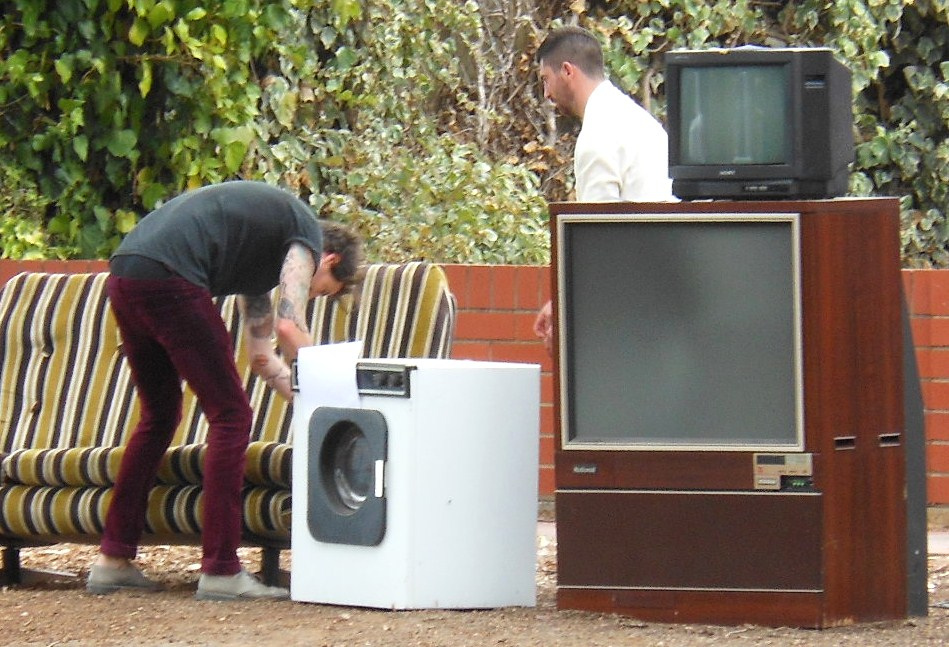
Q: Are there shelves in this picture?
A: No, there are no shelves.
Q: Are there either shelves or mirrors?
A: No, there are no shelves or mirrors.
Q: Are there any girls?
A: No, there are no girls.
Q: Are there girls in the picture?
A: No, there are no girls.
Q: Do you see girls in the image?
A: No, there are no girls.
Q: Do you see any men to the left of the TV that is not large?
A: Yes, there is a man to the left of the TV.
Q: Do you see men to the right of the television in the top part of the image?
A: No, the man is to the left of the television.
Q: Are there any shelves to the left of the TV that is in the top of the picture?
A: No, there is a man to the left of the television.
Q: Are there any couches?
A: Yes, there is a couch.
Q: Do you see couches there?
A: Yes, there is a couch.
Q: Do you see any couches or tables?
A: Yes, there is a couch.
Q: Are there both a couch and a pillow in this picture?
A: No, there is a couch but no pillows.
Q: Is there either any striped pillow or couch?
A: Yes, there is a striped couch.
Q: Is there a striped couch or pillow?
A: Yes, there is a striped couch.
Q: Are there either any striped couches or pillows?
A: Yes, there is a striped couch.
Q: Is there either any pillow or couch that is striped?
A: Yes, the couch is striped.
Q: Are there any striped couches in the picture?
A: Yes, there is a striped couch.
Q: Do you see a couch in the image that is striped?
A: Yes, there is a couch that is striped.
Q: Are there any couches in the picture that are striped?
A: Yes, there is a couch that is striped.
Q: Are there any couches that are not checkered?
A: Yes, there is a striped couch.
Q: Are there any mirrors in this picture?
A: No, there are no mirrors.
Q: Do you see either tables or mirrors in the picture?
A: No, there are no mirrors or tables.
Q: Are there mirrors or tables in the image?
A: No, there are no mirrors or tables.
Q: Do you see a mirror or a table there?
A: No, there are no mirrors or tables.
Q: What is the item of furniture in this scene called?
A: The piece of furniture is a couch.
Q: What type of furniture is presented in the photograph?
A: The furniture is a couch.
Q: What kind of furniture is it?
A: The piece of furniture is a couch.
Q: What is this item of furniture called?
A: This is a couch.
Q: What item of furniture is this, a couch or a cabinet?
A: This is a couch.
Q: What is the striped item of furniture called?
A: The piece of furniture is a couch.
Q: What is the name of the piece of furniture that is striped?
A: The piece of furniture is a couch.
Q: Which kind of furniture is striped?
A: The furniture is a couch.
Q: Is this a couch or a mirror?
A: This is a couch.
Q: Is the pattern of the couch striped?
A: Yes, the couch is striped.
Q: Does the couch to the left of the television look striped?
A: Yes, the couch is striped.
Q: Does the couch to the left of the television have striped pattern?
A: Yes, the couch is striped.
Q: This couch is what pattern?
A: The couch is striped.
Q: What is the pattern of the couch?
A: The couch is striped.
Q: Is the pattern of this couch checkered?
A: No, the couch is striped.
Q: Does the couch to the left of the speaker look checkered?
A: No, the couch is striped.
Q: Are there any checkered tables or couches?
A: No, there is a couch but it is striped.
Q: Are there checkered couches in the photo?
A: No, there is a couch but it is striped.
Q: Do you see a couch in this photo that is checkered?
A: No, there is a couch but it is striped.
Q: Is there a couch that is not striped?
A: No, there is a couch but it is striped.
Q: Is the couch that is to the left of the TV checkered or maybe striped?
A: The couch is striped.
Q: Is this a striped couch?
A: Yes, this is a striped couch.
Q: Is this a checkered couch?
A: No, this is a striped couch.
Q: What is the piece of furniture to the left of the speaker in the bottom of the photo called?
A: The piece of furniture is a couch.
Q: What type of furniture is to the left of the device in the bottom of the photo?
A: The piece of furniture is a couch.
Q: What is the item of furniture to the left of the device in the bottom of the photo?
A: The piece of furniture is a couch.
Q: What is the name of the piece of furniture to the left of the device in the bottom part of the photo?
A: The piece of furniture is a couch.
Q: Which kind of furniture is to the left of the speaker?
A: The piece of furniture is a couch.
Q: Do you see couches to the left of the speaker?
A: Yes, there is a couch to the left of the speaker.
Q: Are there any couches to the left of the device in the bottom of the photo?
A: Yes, there is a couch to the left of the speaker.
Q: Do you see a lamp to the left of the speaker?
A: No, there is a couch to the left of the speaker.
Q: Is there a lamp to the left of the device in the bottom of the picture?
A: No, there is a couch to the left of the speaker.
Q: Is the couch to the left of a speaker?
A: Yes, the couch is to the left of a speaker.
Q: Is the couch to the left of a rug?
A: No, the couch is to the left of a speaker.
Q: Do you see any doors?
A: Yes, there is a door.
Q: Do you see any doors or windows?
A: Yes, there is a door.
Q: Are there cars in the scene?
A: No, there are no cars.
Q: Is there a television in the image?
A: Yes, there is a television.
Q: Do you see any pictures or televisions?
A: Yes, there is a television.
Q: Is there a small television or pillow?
A: Yes, there is a small television.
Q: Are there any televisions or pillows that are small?
A: Yes, the television is small.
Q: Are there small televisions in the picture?
A: Yes, there is a small television.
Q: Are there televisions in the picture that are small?
A: Yes, there is a television that is small.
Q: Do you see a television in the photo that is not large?
A: Yes, there is a small television.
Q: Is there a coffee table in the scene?
A: No, there are no coffee tables.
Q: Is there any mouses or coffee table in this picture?
A: No, there are no coffee tables or computer mousess.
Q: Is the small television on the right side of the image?
A: Yes, the TV is on the right of the image.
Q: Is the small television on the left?
A: No, the TV is on the right of the image.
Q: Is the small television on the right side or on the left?
A: The TV is on the right of the image.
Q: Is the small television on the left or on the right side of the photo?
A: The TV is on the right of the image.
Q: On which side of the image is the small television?
A: The TV is on the right of the image.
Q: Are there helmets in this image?
A: No, there are no helmets.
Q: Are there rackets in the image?
A: No, there are no rackets.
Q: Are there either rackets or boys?
A: No, there are no rackets or boys.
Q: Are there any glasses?
A: No, there are no glasses.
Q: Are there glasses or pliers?
A: No, there are no glasses or pliers.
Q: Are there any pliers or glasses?
A: No, there are no glasses or pliers.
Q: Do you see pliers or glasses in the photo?
A: No, there are no glasses or pliers.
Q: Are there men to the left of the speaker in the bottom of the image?
A: Yes, there is a man to the left of the speaker.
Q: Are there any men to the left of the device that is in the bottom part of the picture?
A: Yes, there is a man to the left of the speaker.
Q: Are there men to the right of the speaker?
A: No, the man is to the left of the speaker.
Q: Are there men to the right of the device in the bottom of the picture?
A: No, the man is to the left of the speaker.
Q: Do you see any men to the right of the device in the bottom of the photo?
A: No, the man is to the left of the speaker.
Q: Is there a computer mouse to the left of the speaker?
A: No, there is a man to the left of the speaker.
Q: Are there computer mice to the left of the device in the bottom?
A: No, there is a man to the left of the speaker.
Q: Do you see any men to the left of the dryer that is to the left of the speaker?
A: Yes, there is a man to the left of the dryer.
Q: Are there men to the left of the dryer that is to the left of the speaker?
A: Yes, there is a man to the left of the dryer.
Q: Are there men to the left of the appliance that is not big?
A: Yes, there is a man to the left of the dryer.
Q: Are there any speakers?
A: Yes, there is a speaker.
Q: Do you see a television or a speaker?
A: Yes, there is a speaker.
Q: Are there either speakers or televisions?
A: Yes, there is a speaker.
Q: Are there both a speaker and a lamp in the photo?
A: No, there is a speaker but no lamps.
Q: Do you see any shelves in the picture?
A: No, there are no shelves.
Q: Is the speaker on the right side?
A: Yes, the speaker is on the right of the image.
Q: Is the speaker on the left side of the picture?
A: No, the speaker is on the right of the image.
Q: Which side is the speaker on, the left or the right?
A: The speaker is on the right of the image.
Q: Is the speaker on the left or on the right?
A: The speaker is on the right of the image.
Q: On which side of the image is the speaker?
A: The speaker is on the right of the image.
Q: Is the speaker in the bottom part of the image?
A: Yes, the speaker is in the bottom of the image.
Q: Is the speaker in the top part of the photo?
A: No, the speaker is in the bottom of the image.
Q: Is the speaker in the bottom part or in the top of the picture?
A: The speaker is in the bottom of the image.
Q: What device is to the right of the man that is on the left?
A: The device is a speaker.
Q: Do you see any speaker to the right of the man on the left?
A: Yes, there is a speaker to the right of the man.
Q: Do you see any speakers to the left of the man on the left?
A: No, the speaker is to the right of the man.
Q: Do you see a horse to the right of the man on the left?
A: No, there is a speaker to the right of the man.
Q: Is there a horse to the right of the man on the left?
A: No, there is a speaker to the right of the man.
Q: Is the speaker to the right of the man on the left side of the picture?
A: Yes, the speaker is to the right of the man.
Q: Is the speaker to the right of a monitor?
A: No, the speaker is to the right of the man.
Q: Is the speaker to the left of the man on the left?
A: No, the speaker is to the right of the man.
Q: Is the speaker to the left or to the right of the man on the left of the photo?
A: The speaker is to the right of the man.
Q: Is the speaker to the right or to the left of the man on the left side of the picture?
A: The speaker is to the right of the man.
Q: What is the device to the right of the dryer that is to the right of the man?
A: The device is a speaker.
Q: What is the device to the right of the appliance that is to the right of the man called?
A: The device is a speaker.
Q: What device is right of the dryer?
A: The device is a speaker.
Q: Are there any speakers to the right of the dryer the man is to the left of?
A: Yes, there is a speaker to the right of the dryer.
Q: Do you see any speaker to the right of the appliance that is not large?
A: Yes, there is a speaker to the right of the dryer.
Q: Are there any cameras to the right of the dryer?
A: No, there is a speaker to the right of the dryer.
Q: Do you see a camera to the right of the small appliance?
A: No, there is a speaker to the right of the dryer.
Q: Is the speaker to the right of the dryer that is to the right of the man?
A: Yes, the speaker is to the right of the dryer.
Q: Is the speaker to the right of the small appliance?
A: Yes, the speaker is to the right of the dryer.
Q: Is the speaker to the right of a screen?
A: No, the speaker is to the right of the dryer.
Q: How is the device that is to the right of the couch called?
A: The device is a speaker.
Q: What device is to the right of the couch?
A: The device is a speaker.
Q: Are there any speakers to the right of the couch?
A: Yes, there is a speaker to the right of the couch.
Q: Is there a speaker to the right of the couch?
A: Yes, there is a speaker to the right of the couch.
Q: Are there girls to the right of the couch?
A: No, there is a speaker to the right of the couch.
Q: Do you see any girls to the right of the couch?
A: No, there is a speaker to the right of the couch.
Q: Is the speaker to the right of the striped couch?
A: Yes, the speaker is to the right of the couch.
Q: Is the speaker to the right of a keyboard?
A: No, the speaker is to the right of the couch.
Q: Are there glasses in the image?
A: No, there are no glasses.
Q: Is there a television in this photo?
A: Yes, there is a television.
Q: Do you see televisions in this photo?
A: Yes, there is a television.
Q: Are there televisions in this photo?
A: Yes, there is a television.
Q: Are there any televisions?
A: Yes, there is a television.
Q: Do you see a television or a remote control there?
A: Yes, there is a television.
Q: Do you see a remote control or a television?
A: Yes, there is a television.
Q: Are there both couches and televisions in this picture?
A: Yes, there are both a television and a couch.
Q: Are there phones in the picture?
A: No, there are no phones.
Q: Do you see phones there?
A: No, there are no phones.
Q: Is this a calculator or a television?
A: This is a television.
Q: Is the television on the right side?
A: Yes, the television is on the right of the image.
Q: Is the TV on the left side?
A: No, the TV is on the right of the image.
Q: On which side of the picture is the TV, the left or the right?
A: The TV is on the right of the image.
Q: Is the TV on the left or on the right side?
A: The TV is on the right of the image.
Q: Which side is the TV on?
A: The TV is on the right of the image.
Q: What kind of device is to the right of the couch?
A: The device is a television.